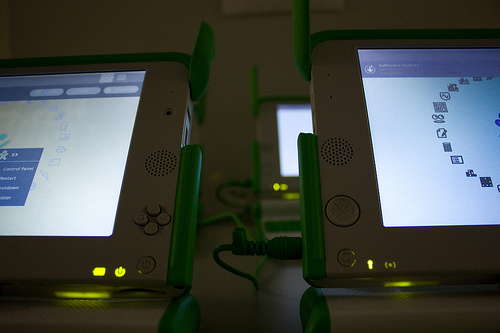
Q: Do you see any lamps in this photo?
A: No, there are no lamps.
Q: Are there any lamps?
A: No, there are no lamps.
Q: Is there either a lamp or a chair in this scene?
A: No, there are no lamps or chairs.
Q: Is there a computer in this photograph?
A: Yes, there is a computer.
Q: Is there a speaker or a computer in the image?
A: Yes, there is a computer.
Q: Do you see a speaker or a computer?
A: Yes, there is a computer.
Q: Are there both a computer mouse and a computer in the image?
A: No, there is a computer but no computer mice.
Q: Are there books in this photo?
A: No, there are no books.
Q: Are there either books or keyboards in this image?
A: No, there are no books or keyboards.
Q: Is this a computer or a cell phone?
A: This is a computer.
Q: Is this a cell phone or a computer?
A: This is a computer.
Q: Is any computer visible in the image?
A: Yes, there is a computer.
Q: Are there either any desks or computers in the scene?
A: Yes, there is a computer.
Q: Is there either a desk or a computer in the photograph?
A: Yes, there is a computer.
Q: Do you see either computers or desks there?
A: Yes, there is a computer.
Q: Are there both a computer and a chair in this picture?
A: No, there is a computer but no chairs.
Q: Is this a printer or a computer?
A: This is a computer.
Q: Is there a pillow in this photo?
A: No, there are no pillows.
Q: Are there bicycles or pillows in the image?
A: No, there are no pillows or bicycles.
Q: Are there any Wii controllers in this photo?
A: No, there are no Wii controllers.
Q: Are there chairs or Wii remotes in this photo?
A: No, there are no Wii remotes or chairs.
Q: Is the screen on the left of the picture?
A: Yes, the screen is on the left of the image.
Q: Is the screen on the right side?
A: No, the screen is on the left of the image.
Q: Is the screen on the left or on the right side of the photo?
A: The screen is on the left of the image.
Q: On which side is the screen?
A: The screen is on the left of the image.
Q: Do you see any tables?
A: Yes, there is a table.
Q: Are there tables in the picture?
A: Yes, there is a table.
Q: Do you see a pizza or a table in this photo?
A: Yes, there is a table.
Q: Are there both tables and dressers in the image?
A: No, there is a table but no dressers.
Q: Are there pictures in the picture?
A: No, there are no pictures.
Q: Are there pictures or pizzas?
A: No, there are no pictures or pizzas.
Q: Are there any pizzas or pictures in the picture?
A: No, there are no pictures or pizzas.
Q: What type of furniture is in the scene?
A: The furniture is a table.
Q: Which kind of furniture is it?
A: The piece of furniture is a table.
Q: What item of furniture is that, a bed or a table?
A: This is a table.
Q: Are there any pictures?
A: No, there are no pictures.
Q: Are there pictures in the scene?
A: No, there are no pictures.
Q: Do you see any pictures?
A: No, there are no pictures.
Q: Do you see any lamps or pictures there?
A: No, there are no pictures or lamps.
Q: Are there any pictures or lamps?
A: No, there are no pictures or lamps.